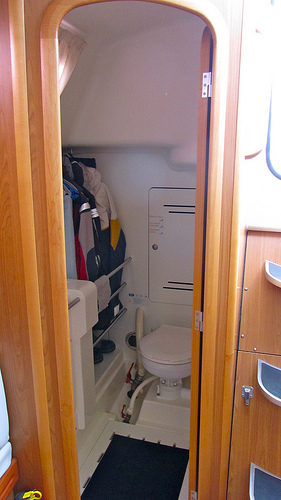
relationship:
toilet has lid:
[139, 185, 196, 403] [137, 322, 193, 361]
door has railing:
[185, 20, 212, 492] [200, 67, 211, 97]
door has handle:
[222, 225, 280, 498] [239, 383, 253, 408]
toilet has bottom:
[139, 185, 196, 403] [151, 379, 182, 402]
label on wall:
[146, 211, 165, 235] [124, 170, 195, 304]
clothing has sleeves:
[86, 167, 125, 317] [63, 187, 120, 271]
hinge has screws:
[201, 73, 210, 99] [201, 71, 209, 94]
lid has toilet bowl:
[137, 322, 193, 361] [132, 323, 192, 385]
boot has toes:
[92, 346, 103, 363] [99, 343, 116, 361]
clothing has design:
[86, 167, 125, 317] [109, 219, 120, 247]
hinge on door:
[202, 73, 210, 95] [188, 28, 211, 460]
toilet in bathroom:
[139, 310, 191, 403] [61, 29, 189, 465]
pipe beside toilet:
[131, 311, 146, 380] [141, 317, 190, 397]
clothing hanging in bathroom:
[86, 167, 125, 317] [61, 29, 189, 465]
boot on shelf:
[92, 346, 103, 363] [96, 349, 125, 399]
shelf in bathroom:
[96, 349, 125, 399] [56, 38, 193, 497]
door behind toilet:
[143, 188, 192, 308] [139, 185, 196, 403]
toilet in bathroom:
[139, 185, 196, 403] [61, 29, 189, 465]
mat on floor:
[76, 433, 192, 499] [79, 413, 189, 496]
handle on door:
[239, 383, 253, 408] [223, 349, 279, 498]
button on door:
[242, 284, 249, 292] [236, 226, 280, 353]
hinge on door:
[201, 73, 210, 99] [184, 24, 217, 497]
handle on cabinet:
[239, 383, 253, 408] [220, 346, 279, 498]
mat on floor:
[76, 433, 192, 497] [76, 406, 187, 498]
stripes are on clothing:
[78, 199, 89, 211] [73, 189, 99, 281]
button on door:
[250, 346, 261, 351] [236, 226, 280, 353]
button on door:
[252, 346, 258, 351] [236, 226, 280, 353]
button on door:
[239, 331, 246, 339] [233, 226, 279, 356]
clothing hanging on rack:
[73, 160, 113, 271] [61, 146, 80, 164]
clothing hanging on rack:
[79, 182, 103, 280] [61, 145, 77, 162]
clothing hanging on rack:
[73, 189, 99, 281] [60, 145, 77, 166]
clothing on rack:
[68, 185, 81, 199] [58, 146, 77, 170]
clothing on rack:
[62, 176, 81, 201] [63, 149, 80, 173]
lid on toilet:
[137, 322, 193, 361] [135, 320, 192, 403]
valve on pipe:
[117, 402, 125, 417] [125, 376, 158, 416]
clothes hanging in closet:
[61, 152, 123, 331] [62, 146, 133, 433]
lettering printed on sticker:
[129, 296, 145, 304] [126, 291, 148, 306]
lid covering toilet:
[137, 322, 193, 361] [137, 323, 193, 400]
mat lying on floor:
[76, 433, 192, 499] [79, 420, 188, 499]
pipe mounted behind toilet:
[129, 311, 146, 395] [137, 323, 193, 400]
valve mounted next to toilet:
[124, 361, 135, 383] [137, 323, 193, 400]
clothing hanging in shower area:
[61, 147, 126, 332] [58, 22, 131, 469]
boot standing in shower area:
[92, 346, 103, 363] [58, 22, 131, 469]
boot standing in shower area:
[92, 333, 114, 353] [58, 22, 131, 469]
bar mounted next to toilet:
[95, 256, 132, 288] [137, 323, 193, 400]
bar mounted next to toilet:
[98, 281, 127, 312] [137, 323, 193, 400]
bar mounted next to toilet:
[93, 307, 126, 346] [137, 323, 193, 400]